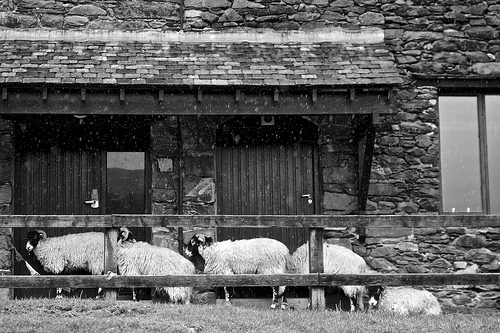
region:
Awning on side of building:
[3, 23, 405, 126]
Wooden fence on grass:
[2, 208, 498, 310]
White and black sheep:
[22, 224, 118, 297]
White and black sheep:
[115, 220, 194, 302]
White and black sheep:
[180, 228, 299, 309]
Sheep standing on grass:
[287, 238, 373, 312]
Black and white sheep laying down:
[364, 281, 445, 320]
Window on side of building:
[430, 72, 498, 225]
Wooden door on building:
[214, 111, 322, 247]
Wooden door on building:
[12, 113, 104, 218]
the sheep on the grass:
[22, 225, 441, 314]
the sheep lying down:
[365, 284, 443, 314]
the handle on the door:
[84, 188, 98, 208]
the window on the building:
[105, 150, 145, 241]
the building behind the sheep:
[0, 0, 498, 308]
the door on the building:
[215, 145, 321, 254]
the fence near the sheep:
[0, 215, 499, 314]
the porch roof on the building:
[0, 30, 404, 243]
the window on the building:
[436, 78, 498, 215]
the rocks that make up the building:
[0, 1, 499, 313]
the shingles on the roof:
[0, 37, 400, 92]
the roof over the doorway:
[0, 35, 397, 85]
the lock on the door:
[298, 187, 314, 209]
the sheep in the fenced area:
[31, 222, 444, 319]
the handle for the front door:
[77, 187, 99, 210]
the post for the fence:
[300, 217, 331, 314]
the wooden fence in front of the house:
[305, 212, 499, 303]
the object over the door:
[256, 115, 284, 132]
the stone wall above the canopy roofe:
[3, 4, 378, 26]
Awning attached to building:
[1, 26, 402, 119]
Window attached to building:
[435, 76, 499, 218]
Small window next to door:
[100, 141, 152, 214]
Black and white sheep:
[20, 223, 112, 300]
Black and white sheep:
[115, 226, 197, 305]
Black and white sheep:
[182, 227, 292, 309]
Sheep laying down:
[364, 278, 442, 316]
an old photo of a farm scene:
[15, 11, 480, 331]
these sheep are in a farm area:
[18, 147, 479, 320]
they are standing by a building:
[16, 27, 478, 242]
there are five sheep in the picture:
[24, 183, 445, 323]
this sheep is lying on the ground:
[340, 261, 454, 316]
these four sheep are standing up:
[25, 205, 367, 309]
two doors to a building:
[10, 103, 352, 225]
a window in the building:
[417, 70, 499, 219]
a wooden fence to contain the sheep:
[8, 205, 486, 322]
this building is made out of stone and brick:
[23, 17, 496, 287]